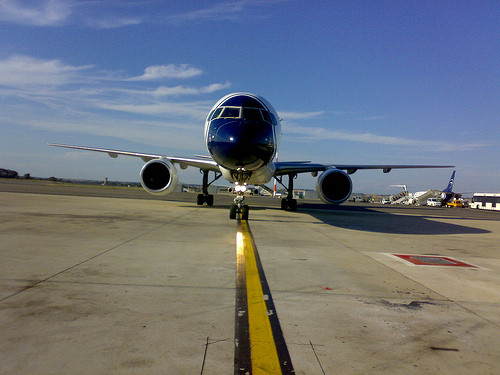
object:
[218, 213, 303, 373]
lines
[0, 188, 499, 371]
road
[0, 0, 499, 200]
sky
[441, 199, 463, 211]
truck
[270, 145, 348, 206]
ground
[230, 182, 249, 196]
headlights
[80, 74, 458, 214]
airplane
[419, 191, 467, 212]
vehicles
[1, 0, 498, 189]
clouds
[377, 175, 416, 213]
ground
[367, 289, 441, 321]
marks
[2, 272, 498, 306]
line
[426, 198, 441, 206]
white van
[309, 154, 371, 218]
engine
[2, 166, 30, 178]
trees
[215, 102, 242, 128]
windshield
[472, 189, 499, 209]
white bus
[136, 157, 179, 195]
engine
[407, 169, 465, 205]
airplane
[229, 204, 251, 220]
landing gear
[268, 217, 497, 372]
ground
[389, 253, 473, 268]
square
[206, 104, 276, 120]
windows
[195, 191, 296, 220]
wheels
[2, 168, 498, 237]
tarmac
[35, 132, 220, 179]
wing